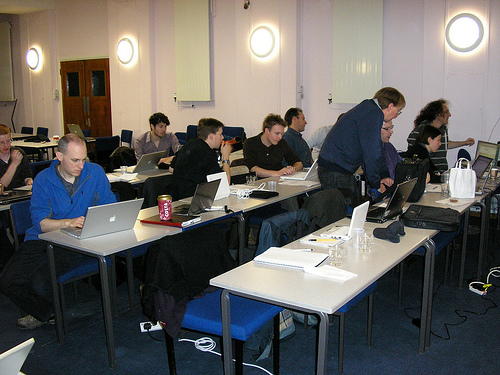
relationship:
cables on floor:
[471, 278, 500, 297] [379, 309, 499, 368]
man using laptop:
[51, 137, 109, 223] [80, 189, 151, 237]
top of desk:
[244, 273, 328, 332] [206, 216, 438, 372]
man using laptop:
[268, 110, 294, 185] [296, 151, 321, 194]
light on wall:
[252, 23, 288, 67] [174, 19, 246, 105]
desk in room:
[18, 130, 371, 285] [11, 7, 500, 319]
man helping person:
[316, 85, 405, 209] [378, 118, 406, 185]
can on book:
[157, 190, 180, 227] [153, 214, 191, 233]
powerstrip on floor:
[127, 299, 163, 343] [379, 309, 499, 368]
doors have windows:
[59, 60, 121, 132] [69, 68, 115, 94]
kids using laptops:
[72, 121, 300, 214] [82, 156, 319, 232]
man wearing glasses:
[341, 83, 389, 201] [398, 107, 403, 120]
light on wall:
[110, 26, 142, 74] [121, 14, 147, 102]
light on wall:
[18, 38, 47, 68] [44, 29, 58, 129]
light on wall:
[439, 13, 494, 62] [419, 16, 488, 115]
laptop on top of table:
[296, 151, 321, 194] [83, 162, 315, 234]